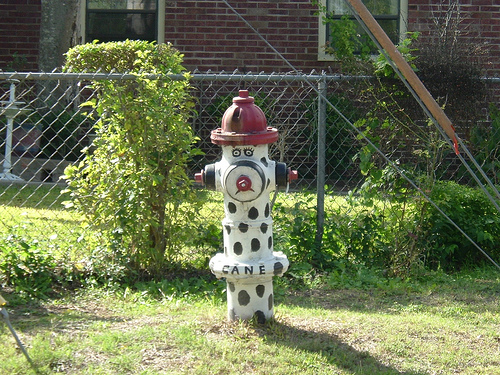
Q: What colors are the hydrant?
A: Black, white, and red.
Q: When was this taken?
A: Daytime.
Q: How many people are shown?
A: 0.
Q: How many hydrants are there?
A: 1.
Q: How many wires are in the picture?
A: 4.